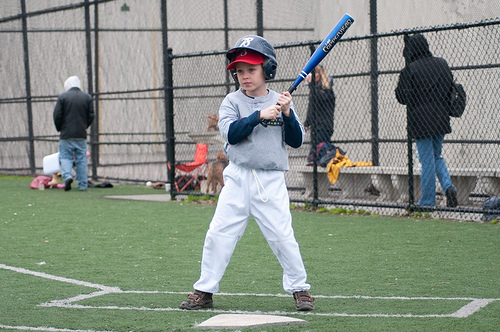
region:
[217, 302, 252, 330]
white home base by player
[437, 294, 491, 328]
white chalk line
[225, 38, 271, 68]
black safety helmet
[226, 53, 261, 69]
red baseball hat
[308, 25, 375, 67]
blue tip of ball bat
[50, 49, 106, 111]
white hood of jacket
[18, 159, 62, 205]
child in pink on ground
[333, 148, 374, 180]
yellow jacket on bench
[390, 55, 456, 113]
black jacket on person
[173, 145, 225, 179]
red seat by fence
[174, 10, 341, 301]
The kid is playing baseball.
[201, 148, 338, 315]
The kid's pants are white.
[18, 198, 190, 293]
The grass is green.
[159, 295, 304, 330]
The plate is white.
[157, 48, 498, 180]
This is a chain link fence.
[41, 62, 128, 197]
The man has a hood up.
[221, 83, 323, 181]
The shirt is gray and blue.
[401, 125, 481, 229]
The woman has blue jeans.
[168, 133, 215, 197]
The chair is red.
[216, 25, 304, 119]
The kid has on a helmet.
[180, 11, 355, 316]
Young boy holding a baseball bat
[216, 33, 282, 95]
Boy wearing red hat and blue helmet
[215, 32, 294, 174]
Young boy wearing gray jersey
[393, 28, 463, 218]
Woman wearing black coat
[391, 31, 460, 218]
Woman wearing blue jeans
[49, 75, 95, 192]
Man wearing black coat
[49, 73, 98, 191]
Man wearing blue jeans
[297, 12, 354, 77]
The baseball bat is blue and white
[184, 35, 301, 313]
Boy wearing white sweat pants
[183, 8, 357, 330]
Boy standing at home base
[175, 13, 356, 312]
young boy holding a blue bat on a baseball field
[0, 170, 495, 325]
green astroturf on baseball field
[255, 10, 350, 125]
blue baseball bat being held by young boy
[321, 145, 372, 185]
yellow jacket on a bench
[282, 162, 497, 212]
cement bench behind a fence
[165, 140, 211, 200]
red pop-up chair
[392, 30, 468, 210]
adult wearing a black jacket and denim jeans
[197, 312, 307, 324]
home plate on a baseball field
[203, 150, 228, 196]
medium-sized brown dog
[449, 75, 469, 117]
black backpack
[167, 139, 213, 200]
RED CAMPING CHAIR THAT IS OPEN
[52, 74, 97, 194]
MAN WITH A HOOD OVER HIS HEAD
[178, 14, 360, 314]
BOY HOLDING A BASEBALL BAT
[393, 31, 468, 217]
PERSON WEARING BLUE JEANS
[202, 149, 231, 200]
BROWN DOG IN THE BACKGROUND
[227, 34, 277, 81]
BATTERS HELMET WITH THE LETTER B ON THE FRONT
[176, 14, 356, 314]
BOY WEARING WHITE PANTS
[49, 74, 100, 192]
MAN WEARING A BLACK COAT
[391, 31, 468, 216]
PERSON HOLDING A BAG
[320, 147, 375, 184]
YELLOW JACKET ON A BENCH